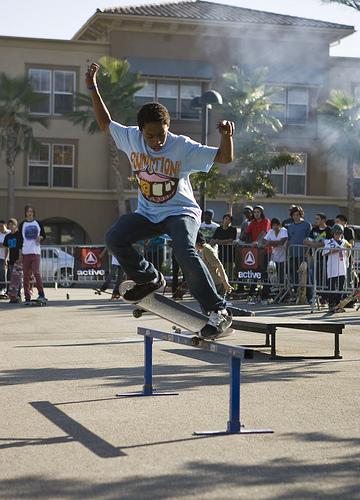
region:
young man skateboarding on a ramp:
[70, 57, 293, 447]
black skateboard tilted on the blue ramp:
[112, 274, 264, 440]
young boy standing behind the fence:
[321, 221, 359, 314]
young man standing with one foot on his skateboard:
[16, 203, 57, 307]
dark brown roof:
[100, 1, 344, 29]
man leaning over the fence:
[257, 216, 295, 295]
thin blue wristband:
[82, 82, 103, 94]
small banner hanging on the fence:
[68, 240, 107, 278]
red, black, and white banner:
[230, 243, 269, 285]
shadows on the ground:
[1, 432, 358, 498]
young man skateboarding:
[59, 48, 261, 348]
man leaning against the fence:
[255, 216, 293, 303]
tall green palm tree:
[56, 54, 167, 251]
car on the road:
[10, 245, 97, 285]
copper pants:
[18, 251, 50, 301]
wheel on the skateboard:
[186, 332, 204, 346]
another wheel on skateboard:
[131, 304, 148, 323]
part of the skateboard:
[154, 294, 202, 324]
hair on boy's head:
[146, 107, 171, 115]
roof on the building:
[132, 2, 256, 17]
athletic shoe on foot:
[208, 312, 221, 336]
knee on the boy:
[172, 248, 201, 261]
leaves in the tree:
[241, 93, 282, 125]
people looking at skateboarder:
[245, 204, 313, 238]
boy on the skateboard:
[72, 62, 257, 343]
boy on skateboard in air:
[70, 54, 281, 348]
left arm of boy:
[215, 116, 246, 168]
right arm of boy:
[78, 58, 110, 131]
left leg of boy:
[171, 243, 230, 345]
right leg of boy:
[116, 250, 161, 299]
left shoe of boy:
[200, 300, 227, 335]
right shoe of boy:
[128, 268, 167, 310]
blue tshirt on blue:
[113, 141, 190, 215]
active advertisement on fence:
[229, 241, 267, 281]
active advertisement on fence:
[70, 244, 112, 284]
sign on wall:
[228, 245, 275, 281]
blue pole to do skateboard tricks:
[113, 321, 280, 442]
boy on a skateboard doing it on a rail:
[60, 60, 249, 353]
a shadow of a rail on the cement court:
[26, 388, 212, 463]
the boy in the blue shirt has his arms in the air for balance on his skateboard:
[87, 72, 262, 337]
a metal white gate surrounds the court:
[9, 239, 357, 286]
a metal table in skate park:
[231, 312, 344, 358]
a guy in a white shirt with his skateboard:
[19, 205, 45, 317]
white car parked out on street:
[3, 209, 72, 303]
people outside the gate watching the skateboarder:
[3, 206, 358, 384]